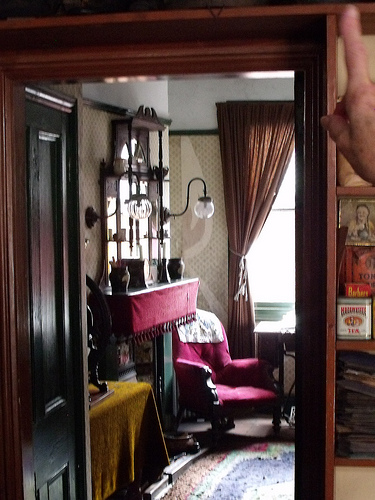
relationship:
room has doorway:
[0, 1, 371, 499] [1, 2, 353, 498]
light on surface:
[203, 454, 293, 498] [119, 408, 313, 498]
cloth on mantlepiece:
[103, 277, 201, 349] [97, 269, 199, 344]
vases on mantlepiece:
[108, 266, 130, 293] [102, 275, 201, 345]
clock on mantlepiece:
[127, 259, 150, 288] [102, 275, 201, 345]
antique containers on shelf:
[107, 119, 206, 294] [333, 181, 371, 477]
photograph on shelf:
[339, 200, 373, 247] [333, 181, 371, 477]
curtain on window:
[213, 99, 291, 356] [247, 116, 293, 320]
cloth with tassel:
[102, 278, 199, 344] [193, 312, 196, 321]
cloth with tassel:
[102, 278, 199, 344] [186, 313, 189, 323]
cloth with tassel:
[102, 278, 199, 344] [168, 320, 171, 331]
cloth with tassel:
[102, 278, 199, 344] [159, 324, 164, 335]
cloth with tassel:
[102, 278, 199, 344] [136, 331, 142, 345]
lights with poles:
[97, 143, 232, 231] [104, 155, 217, 259]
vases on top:
[102, 255, 188, 293] [92, 264, 203, 296]